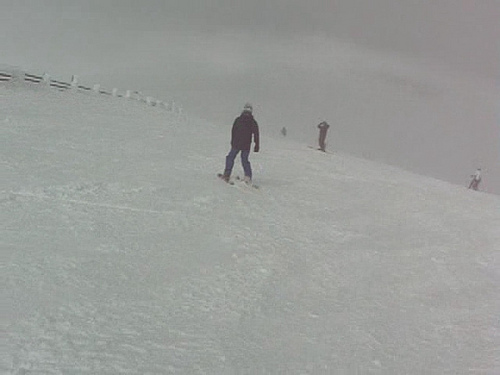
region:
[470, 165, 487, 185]
the person is wearing a white coat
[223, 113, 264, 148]
the person is wearing a black coat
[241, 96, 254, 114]
the person is wearing a white cap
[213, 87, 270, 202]
the person is standing on a slope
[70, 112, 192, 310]
the slope is steep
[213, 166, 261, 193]
the person is on skis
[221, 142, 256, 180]
the person is wearing blue jeans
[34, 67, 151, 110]
the fence is short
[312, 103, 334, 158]
the person has their arms raised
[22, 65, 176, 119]
the fence is covered in snow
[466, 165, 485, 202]
a person wearing white on top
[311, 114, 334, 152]
a person stands with hands on head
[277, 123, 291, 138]
a skier barely visiable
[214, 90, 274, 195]
a skier wears blue jeans and black coat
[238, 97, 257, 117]
a white hat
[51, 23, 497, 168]
hazy picture from snow falling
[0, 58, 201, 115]
snowy fence on hilltop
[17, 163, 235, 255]
tracks from skies in the snow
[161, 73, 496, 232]
the curve of the ski area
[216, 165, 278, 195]
wearing snow covered skis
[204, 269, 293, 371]
the snow is white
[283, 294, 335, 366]
the snow is white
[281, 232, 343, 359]
the snow is white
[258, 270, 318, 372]
the snow is white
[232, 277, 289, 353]
the snow is white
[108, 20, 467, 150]
the sky is very grey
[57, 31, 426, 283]
it is lightly snowing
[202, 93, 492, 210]
the people are skiing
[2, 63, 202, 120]
a snowy fence to the left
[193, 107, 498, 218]
four people out in the snow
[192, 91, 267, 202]
the person is cold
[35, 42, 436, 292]
this is the winter season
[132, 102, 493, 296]
there is more snow in the distance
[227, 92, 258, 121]
the person is wearing a hat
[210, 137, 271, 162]
the person is wearing gloves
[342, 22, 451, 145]
the sky is gloomy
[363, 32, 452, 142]
the sky is white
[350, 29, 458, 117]
the sky is cloudy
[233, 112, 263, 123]
the person is wearing a scarf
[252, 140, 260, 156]
the person is wearing a black glove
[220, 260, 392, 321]
the snow is white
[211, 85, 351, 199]
the people are on a hill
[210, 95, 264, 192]
the person is on skis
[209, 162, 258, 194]
the skis are black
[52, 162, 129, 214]
the tracks are in the snow